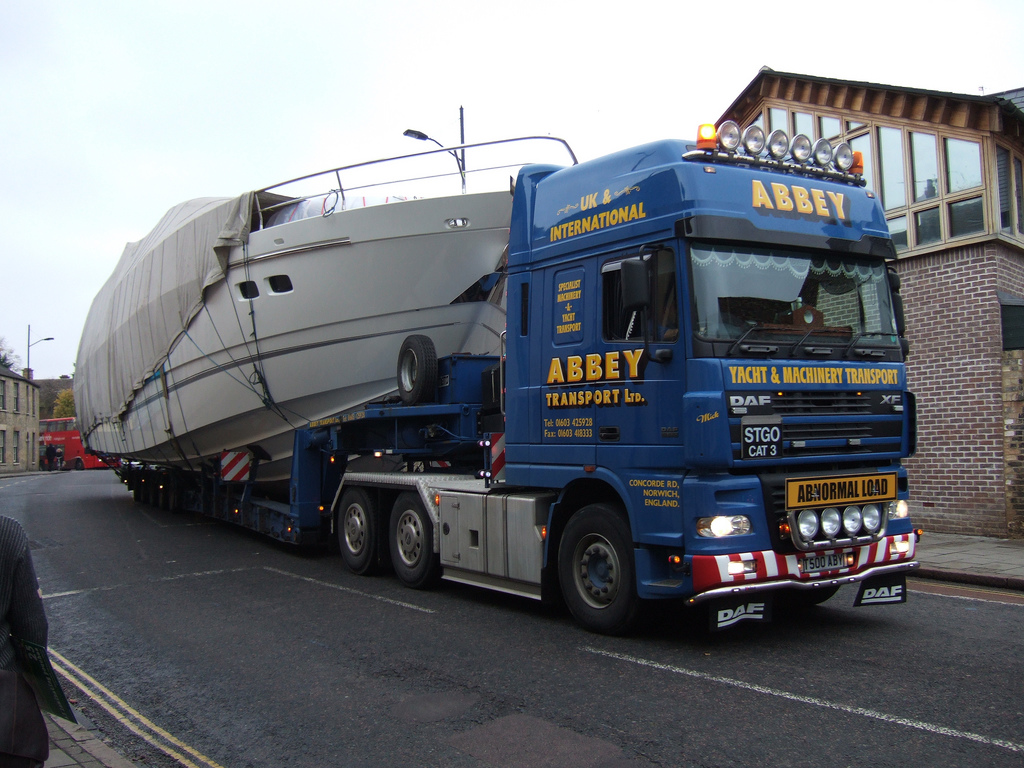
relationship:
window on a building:
[268, 275, 293, 293] [4, 354, 48, 480]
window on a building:
[685, 240, 898, 345] [4, 354, 48, 480]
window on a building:
[944, 137, 983, 194] [4, 354, 48, 480]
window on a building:
[767, 91, 796, 147] [4, 354, 48, 480]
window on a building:
[819, 117, 841, 139] [4, 354, 48, 480]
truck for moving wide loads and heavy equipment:
[67, 122, 931, 642] [61, 128, 583, 473]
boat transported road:
[65, 128, 585, 473] [4, 459, 1022, 759]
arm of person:
[6, 514, 52, 671] [2, 508, 78, 763]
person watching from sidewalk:
[2, 508, 78, 763] [37, 697, 134, 761]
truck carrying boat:
[67, 122, 931, 642] [65, 128, 585, 473]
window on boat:
[239, 281, 259, 299] [65, 128, 585, 473]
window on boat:
[230, 273, 265, 308] [65, 128, 585, 473]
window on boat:
[268, 275, 293, 293] [65, 128, 585, 473]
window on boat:
[944, 137, 983, 194] [65, 128, 585, 473]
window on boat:
[600, 248, 679, 343] [65, 128, 585, 473]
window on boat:
[685, 240, 898, 345] [65, 128, 585, 473]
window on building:
[262, 269, 299, 298] [2, 360, 52, 480]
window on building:
[767, 108, 786, 136] [2, 360, 52, 480]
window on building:
[914, 206, 942, 246] [2, 360, 52, 480]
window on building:
[909, 132, 939, 202] [2, 360, 52, 480]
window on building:
[944, 137, 983, 194] [2, 360, 52, 480]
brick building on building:
[714, 65, 1024, 540] [2, 360, 52, 480]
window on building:
[600, 248, 679, 343] [2, 360, 52, 480]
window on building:
[685, 240, 898, 345] [2, 360, 52, 480]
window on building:
[907, 197, 949, 253] [2, 360, 52, 480]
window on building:
[794, 112, 814, 146] [2, 360, 52, 480]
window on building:
[905, 122, 947, 209] [2, 360, 52, 480]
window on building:
[767, 100, 798, 142] [2, 360, 52, 480]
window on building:
[814, 96, 847, 148] [2, 360, 52, 480]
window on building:
[874, 114, 920, 215] [2, 360, 52, 480]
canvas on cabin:
[67, 188, 308, 437] [80, 182, 520, 468]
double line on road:
[47, 635, 226, 765] [4, 459, 1022, 759]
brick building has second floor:
[710, 59, 1022, 554] [704, 61, 1021, 271]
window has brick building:
[841, 110, 870, 141] [710, 59, 1022, 554]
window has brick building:
[878, 208, 916, 254] [710, 59, 1022, 554]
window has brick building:
[761, 94, 805, 142] [710, 59, 1022, 554]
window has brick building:
[876, 125, 906, 212] [710, 59, 1022, 554]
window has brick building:
[946, 132, 988, 202] [710, 59, 1022, 554]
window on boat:
[909, 132, 939, 202] [65, 128, 585, 473]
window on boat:
[597, 241, 680, 342] [65, 128, 585, 473]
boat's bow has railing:
[355, 178, 520, 396] [254, 132, 585, 229]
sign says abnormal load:
[847, 570, 913, 614] [781, 473, 907, 506]